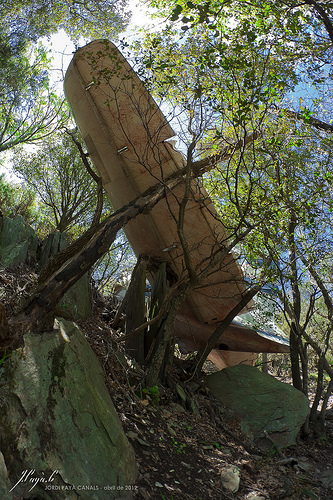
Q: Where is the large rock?
A: On the hillside.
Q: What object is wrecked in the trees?
A: A plane wing.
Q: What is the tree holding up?
A: A plane wing.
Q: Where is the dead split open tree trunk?
A: Under the plane wing.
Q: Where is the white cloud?
A: In the left sky.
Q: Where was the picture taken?
A: In a forest.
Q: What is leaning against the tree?
A: A wing.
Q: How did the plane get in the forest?
A: It crashed.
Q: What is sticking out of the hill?
A: Rocks.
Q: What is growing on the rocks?
A: Moss.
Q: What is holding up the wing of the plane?
A: A branch.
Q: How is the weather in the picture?
A: Sunny.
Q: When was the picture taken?
A: 2012.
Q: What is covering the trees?
A: Leaves.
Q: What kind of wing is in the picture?
A: A airplane.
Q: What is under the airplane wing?
A: A green rock.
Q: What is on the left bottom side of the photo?
A: A large rock.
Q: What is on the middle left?
A: Two large boulders.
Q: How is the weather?
A: Sunny.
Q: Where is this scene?
A: The forest.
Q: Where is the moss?
A: On a boulder.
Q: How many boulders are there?
A: Four.